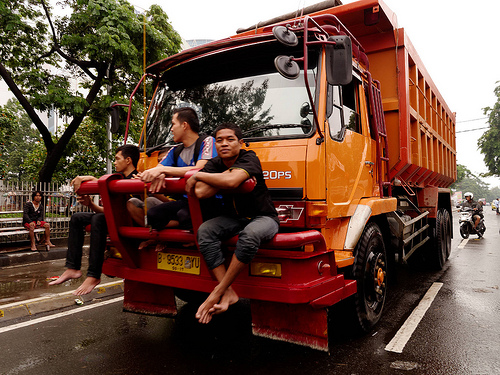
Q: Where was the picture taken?
A: It was taken at the road.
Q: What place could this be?
A: It is a road.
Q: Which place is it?
A: It is a road.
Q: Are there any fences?
A: Yes, there is a fence.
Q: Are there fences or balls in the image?
A: Yes, there is a fence.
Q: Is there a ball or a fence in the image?
A: Yes, there is a fence.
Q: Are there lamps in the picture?
A: No, there are no lamps.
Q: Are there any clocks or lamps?
A: No, there are no lamps or clocks.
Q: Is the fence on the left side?
A: Yes, the fence is on the left of the image.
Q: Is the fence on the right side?
A: No, the fence is on the left of the image.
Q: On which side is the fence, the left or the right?
A: The fence is on the left of the image.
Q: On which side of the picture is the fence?
A: The fence is on the left of the image.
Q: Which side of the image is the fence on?
A: The fence is on the left of the image.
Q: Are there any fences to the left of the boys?
A: Yes, there is a fence to the left of the boys.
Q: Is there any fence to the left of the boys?
A: Yes, there is a fence to the left of the boys.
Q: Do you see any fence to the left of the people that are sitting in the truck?
A: Yes, there is a fence to the left of the boys.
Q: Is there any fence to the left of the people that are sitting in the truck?
A: Yes, there is a fence to the left of the boys.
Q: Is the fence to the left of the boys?
A: Yes, the fence is to the left of the boys.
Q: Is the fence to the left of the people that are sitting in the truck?
A: Yes, the fence is to the left of the boys.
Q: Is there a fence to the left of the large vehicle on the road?
A: Yes, there is a fence to the left of the truck.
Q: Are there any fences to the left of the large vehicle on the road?
A: Yes, there is a fence to the left of the truck.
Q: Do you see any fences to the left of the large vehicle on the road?
A: Yes, there is a fence to the left of the truck.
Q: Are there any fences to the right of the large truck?
A: No, the fence is to the left of the truck.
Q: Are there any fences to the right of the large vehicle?
A: No, the fence is to the left of the truck.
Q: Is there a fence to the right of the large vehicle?
A: No, the fence is to the left of the truck.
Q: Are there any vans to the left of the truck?
A: No, there is a fence to the left of the truck.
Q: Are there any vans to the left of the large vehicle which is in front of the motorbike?
A: No, there is a fence to the left of the truck.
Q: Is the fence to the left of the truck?
A: Yes, the fence is to the left of the truck.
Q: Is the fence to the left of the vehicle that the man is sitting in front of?
A: Yes, the fence is to the left of the truck.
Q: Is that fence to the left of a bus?
A: No, the fence is to the left of the truck.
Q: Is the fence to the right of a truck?
A: No, the fence is to the left of a truck.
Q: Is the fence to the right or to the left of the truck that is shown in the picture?
A: The fence is to the left of the truck.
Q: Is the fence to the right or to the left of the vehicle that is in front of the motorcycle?
A: The fence is to the left of the truck.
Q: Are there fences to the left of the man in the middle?
A: Yes, there is a fence to the left of the man.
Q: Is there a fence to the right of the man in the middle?
A: No, the fence is to the left of the man.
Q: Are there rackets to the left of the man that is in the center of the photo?
A: No, there is a fence to the left of the man.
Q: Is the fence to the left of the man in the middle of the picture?
A: Yes, the fence is to the left of the man.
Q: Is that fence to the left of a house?
A: No, the fence is to the left of the man.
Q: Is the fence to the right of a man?
A: No, the fence is to the left of a man.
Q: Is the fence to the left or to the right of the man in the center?
A: The fence is to the left of the man.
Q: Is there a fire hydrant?
A: No, there are no fire hydrants.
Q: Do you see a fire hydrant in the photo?
A: No, there are no fire hydrants.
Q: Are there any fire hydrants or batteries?
A: No, there are no fire hydrants or batteries.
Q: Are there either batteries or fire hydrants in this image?
A: No, there are no fire hydrants or batteries.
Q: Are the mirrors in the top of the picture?
A: Yes, the mirrors are in the top of the image.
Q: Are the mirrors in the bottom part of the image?
A: No, the mirrors are in the top of the image.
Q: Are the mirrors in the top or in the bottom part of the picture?
A: The mirrors are in the top of the image.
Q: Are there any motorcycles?
A: Yes, there is a motorcycle.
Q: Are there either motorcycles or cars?
A: Yes, there is a motorcycle.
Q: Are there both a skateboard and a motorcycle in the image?
A: No, there is a motorcycle but no skateboards.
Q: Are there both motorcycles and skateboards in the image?
A: No, there is a motorcycle but no skateboards.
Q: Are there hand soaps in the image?
A: No, there are no hand soaps.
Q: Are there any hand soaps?
A: No, there are no hand soaps.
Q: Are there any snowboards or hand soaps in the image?
A: No, there are no hand soaps or snowboards.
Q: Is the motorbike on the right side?
A: Yes, the motorbike is on the right of the image.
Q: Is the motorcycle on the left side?
A: No, the motorcycle is on the right of the image.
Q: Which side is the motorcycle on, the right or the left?
A: The motorcycle is on the right of the image.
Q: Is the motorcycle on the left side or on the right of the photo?
A: The motorcycle is on the right of the image.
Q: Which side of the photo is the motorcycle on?
A: The motorcycle is on the right of the image.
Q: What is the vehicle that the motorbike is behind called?
A: The vehicle is a truck.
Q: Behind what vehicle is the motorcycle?
A: The motorbike is behind the truck.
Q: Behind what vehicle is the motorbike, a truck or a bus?
A: The motorbike is behind a truck.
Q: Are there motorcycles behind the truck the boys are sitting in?
A: Yes, there is a motorcycle behind the truck.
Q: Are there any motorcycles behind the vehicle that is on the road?
A: Yes, there is a motorcycle behind the truck.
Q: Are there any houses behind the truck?
A: No, there is a motorcycle behind the truck.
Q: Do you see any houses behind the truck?
A: No, there is a motorcycle behind the truck.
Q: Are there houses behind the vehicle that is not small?
A: No, there is a motorcycle behind the truck.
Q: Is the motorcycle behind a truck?
A: Yes, the motorcycle is behind a truck.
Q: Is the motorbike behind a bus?
A: No, the motorbike is behind a truck.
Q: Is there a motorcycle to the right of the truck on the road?
A: Yes, there is a motorcycle to the right of the truck.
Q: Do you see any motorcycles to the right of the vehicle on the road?
A: Yes, there is a motorcycle to the right of the truck.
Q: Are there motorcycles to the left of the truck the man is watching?
A: No, the motorcycle is to the right of the truck.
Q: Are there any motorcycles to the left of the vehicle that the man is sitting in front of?
A: No, the motorcycle is to the right of the truck.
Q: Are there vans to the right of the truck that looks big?
A: No, there is a motorcycle to the right of the truck.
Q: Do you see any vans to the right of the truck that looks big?
A: No, there is a motorcycle to the right of the truck.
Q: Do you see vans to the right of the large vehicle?
A: No, there is a motorcycle to the right of the truck.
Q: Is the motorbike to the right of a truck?
A: Yes, the motorbike is to the right of a truck.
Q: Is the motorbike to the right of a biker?
A: No, the motorbike is to the right of a truck.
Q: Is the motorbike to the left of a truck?
A: No, the motorbike is to the right of a truck.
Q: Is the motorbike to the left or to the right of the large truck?
A: The motorbike is to the right of the truck.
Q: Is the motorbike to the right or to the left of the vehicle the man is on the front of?
A: The motorbike is to the right of the truck.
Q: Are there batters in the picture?
A: No, there are no batters.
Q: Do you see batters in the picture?
A: No, there are no batters.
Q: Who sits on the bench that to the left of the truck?
A: The man sits on the bench.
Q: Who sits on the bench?
A: The man sits on the bench.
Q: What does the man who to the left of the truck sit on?
A: The man sits on the bench.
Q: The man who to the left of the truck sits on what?
A: The man sits on the bench.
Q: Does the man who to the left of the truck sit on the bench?
A: Yes, the man sits on the bench.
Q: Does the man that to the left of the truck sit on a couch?
A: No, the man sits on the bench.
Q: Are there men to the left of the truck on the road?
A: Yes, there is a man to the left of the truck.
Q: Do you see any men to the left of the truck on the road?
A: Yes, there is a man to the left of the truck.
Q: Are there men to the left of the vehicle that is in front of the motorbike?
A: Yes, there is a man to the left of the truck.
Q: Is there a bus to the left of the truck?
A: No, there is a man to the left of the truck.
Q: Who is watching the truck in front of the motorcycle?
A: The man is watching the truck.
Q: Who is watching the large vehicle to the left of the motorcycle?
A: The man is watching the truck.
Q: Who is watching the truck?
A: The man is watching the truck.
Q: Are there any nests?
A: No, there are no nests.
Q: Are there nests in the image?
A: No, there are no nests.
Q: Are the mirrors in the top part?
A: Yes, the mirrors are in the top of the image.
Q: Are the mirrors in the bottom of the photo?
A: No, the mirrors are in the top of the image.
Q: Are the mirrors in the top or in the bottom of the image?
A: The mirrors are in the top of the image.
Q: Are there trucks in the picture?
A: Yes, there is a truck.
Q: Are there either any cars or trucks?
A: Yes, there is a truck.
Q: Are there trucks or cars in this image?
A: Yes, there is a truck.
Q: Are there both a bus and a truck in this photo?
A: No, there is a truck but no buses.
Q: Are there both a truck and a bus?
A: No, there is a truck but no buses.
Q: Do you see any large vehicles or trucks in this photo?
A: Yes, there is a large truck.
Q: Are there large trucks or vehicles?
A: Yes, there is a large truck.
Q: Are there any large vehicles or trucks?
A: Yes, there is a large truck.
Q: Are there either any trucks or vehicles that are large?
A: Yes, the truck is large.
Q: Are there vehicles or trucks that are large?
A: Yes, the truck is large.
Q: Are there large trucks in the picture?
A: Yes, there is a large truck.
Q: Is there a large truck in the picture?
A: Yes, there is a large truck.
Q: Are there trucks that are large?
A: Yes, there is a truck that is large.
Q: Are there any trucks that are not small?
A: Yes, there is a large truck.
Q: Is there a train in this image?
A: No, there are no trains.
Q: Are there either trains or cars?
A: No, there are no trains or cars.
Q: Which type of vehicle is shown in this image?
A: The vehicle is a truck.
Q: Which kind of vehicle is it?
A: The vehicle is a truck.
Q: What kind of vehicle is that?
A: This is a truck.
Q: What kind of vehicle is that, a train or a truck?
A: This is a truck.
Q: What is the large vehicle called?
A: The vehicle is a truck.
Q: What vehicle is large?
A: The vehicle is a truck.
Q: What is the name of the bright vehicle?
A: The vehicle is a truck.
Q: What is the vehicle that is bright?
A: The vehicle is a truck.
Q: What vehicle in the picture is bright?
A: The vehicle is a truck.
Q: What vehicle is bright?
A: The vehicle is a truck.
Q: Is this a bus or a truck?
A: This is a truck.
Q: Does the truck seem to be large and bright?
A: Yes, the truck is large and bright.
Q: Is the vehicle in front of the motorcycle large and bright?
A: Yes, the truck is large and bright.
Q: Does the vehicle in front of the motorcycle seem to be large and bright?
A: Yes, the truck is large and bright.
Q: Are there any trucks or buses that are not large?
A: No, there is a truck but it is large.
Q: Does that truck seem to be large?
A: Yes, the truck is large.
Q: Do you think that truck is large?
A: Yes, the truck is large.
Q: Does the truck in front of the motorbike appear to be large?
A: Yes, the truck is large.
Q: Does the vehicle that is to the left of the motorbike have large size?
A: Yes, the truck is large.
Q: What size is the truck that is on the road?
A: The truck is large.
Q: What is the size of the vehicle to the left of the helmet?
A: The truck is large.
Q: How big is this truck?
A: The truck is large.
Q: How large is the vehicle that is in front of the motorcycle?
A: The truck is large.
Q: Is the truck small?
A: No, the truck is large.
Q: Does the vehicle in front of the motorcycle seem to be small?
A: No, the truck is large.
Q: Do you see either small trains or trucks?
A: No, there is a truck but it is large.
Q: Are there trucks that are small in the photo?
A: No, there is a truck but it is large.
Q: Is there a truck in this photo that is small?
A: No, there is a truck but it is large.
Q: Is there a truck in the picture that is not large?
A: No, there is a truck but it is large.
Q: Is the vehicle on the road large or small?
A: The truck is large.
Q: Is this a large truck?
A: Yes, this is a large truck.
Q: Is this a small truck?
A: No, this is a large truck.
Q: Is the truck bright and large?
A: Yes, the truck is bright and large.